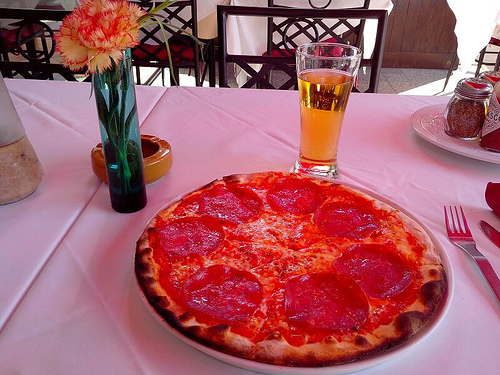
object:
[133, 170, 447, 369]
pizza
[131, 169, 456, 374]
plate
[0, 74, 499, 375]
table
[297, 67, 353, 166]
beer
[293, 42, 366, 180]
glass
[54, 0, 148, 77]
flowers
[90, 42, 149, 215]
vase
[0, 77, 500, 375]
tablecloth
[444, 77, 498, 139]
spices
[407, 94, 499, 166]
plate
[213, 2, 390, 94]
chair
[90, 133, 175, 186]
ashtray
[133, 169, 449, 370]
crust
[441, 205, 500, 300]
fork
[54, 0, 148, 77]
petals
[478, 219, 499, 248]
knife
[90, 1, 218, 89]
chairs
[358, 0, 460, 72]
wall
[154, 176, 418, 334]
pepperoni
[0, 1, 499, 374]
restaurant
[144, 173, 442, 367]
cheese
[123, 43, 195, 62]
cushions